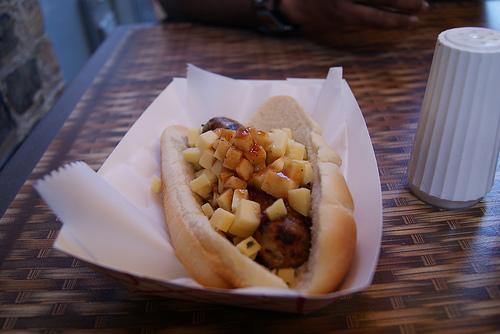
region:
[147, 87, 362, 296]
hot dog on bun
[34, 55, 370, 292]
whtie wax paper under hot dog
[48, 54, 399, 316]
paper tray holding hot dog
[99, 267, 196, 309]
red and white stripe design on paper tray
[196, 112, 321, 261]
white cubed hot dog topping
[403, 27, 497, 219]
salt shaker on table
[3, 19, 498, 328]
restaurant dining table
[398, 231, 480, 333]
wicker pattern on place mat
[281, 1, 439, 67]
hand on table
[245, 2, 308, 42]
watch on wrist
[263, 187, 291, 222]
Piece of white cheese on hot dog.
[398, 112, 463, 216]
Salt shaker on table.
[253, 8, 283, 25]
Watch on person's hand.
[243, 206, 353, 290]
Hot dog on white bun.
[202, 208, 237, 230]
White cheese on hot dog.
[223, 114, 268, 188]
Dark sauce on top of hot dog.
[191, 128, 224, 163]
White cheese on hot dog.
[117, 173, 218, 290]
Hot dog on top of white paper.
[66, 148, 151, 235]
White paper on top of white card board.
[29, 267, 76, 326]
Brown colored table top.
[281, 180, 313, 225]
this is a piece of fruit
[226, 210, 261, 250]
this is a piece of fruit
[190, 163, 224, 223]
this is a piece of fruit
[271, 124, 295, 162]
this is a piece of fruit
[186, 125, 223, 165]
this is a piece of fruit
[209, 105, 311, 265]
this is a sausage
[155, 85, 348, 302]
this is a hot dog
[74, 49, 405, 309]
the plate is white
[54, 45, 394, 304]
this is a paper towel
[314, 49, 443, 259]
this is a table mat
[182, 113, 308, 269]
The sausage in the bun.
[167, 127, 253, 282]
The left side of the bun.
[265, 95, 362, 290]
The right side of the bun.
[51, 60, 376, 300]
The cardboard holding the sausage in the bun.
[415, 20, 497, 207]
The salt shaker on the table.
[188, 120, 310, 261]
The chunks of cheese on the sausage.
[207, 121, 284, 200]
The sauce on the chunks of cheese.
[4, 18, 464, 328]
The table the food is placed on.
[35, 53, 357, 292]
The white paper under the bun.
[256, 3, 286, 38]
The watch of the person sitting at the table.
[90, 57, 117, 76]
this is a table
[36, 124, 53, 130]
the table is wooden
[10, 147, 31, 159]
the table is brown in color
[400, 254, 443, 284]
this is a table mat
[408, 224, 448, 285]
the mat is brown in color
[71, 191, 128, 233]
this is a paper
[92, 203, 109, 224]
the paper is white in color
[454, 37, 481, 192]
this is a salt shaker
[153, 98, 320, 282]
this is some food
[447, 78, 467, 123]
the shaker is white in color